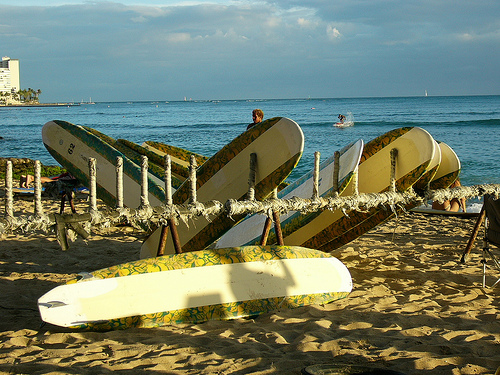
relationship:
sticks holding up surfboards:
[71, 154, 498, 213] [37, 118, 469, 357]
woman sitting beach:
[435, 179, 470, 210] [0, 179, 499, 373]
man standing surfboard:
[338, 112, 345, 123] [331, 119, 353, 129]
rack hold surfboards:
[2, 146, 499, 261] [42, 119, 463, 334]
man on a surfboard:
[338, 114, 346, 124] [333, 121, 353, 125]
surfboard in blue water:
[333, 121, 353, 125] [1, 95, 492, 224]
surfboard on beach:
[37, 245, 352, 331] [0, 179, 499, 373]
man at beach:
[246, 109, 265, 131] [5, 152, 499, 370]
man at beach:
[240, 102, 277, 195] [6, 211, 498, 371]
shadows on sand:
[374, 227, 471, 249] [5, 215, 497, 374]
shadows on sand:
[281, 299, 491, 339] [5, 215, 497, 374]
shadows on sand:
[6, 227, 136, 267] [5, 215, 497, 374]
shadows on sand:
[172, 328, 362, 373] [5, 215, 497, 374]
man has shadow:
[246, 109, 265, 131] [216, 231, 346, 348]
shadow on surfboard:
[183, 245, 298, 326] [34, 245, 352, 325]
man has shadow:
[246, 109, 265, 131] [206, 237, 316, 320]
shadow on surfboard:
[206, 237, 316, 320] [33, 232, 358, 338]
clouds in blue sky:
[262, 12, 344, 54] [0, 0, 500, 103]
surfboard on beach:
[34, 245, 352, 325] [0, 179, 499, 373]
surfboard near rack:
[34, 245, 352, 325] [61, 154, 499, 281]